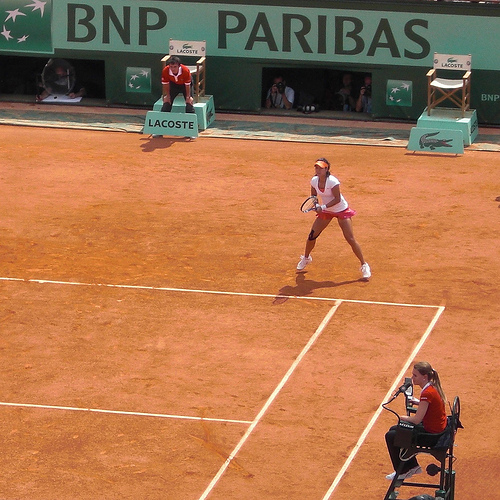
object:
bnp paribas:
[66, 3, 441, 60]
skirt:
[315, 208, 356, 216]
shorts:
[315, 206, 357, 219]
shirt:
[311, 175, 349, 214]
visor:
[314, 161, 328, 169]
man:
[35, 66, 86, 101]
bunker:
[1, 54, 107, 108]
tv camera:
[41, 55, 76, 95]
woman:
[384, 361, 447, 480]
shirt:
[418, 381, 447, 434]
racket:
[300, 196, 320, 213]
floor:
[3, 126, 294, 286]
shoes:
[360, 261, 371, 280]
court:
[0, 128, 500, 500]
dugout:
[262, 66, 373, 114]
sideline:
[200, 298, 342, 500]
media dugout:
[0, 55, 105, 101]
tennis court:
[1, 125, 498, 497]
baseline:
[1, 277, 446, 308]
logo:
[0, 1, 49, 45]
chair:
[426, 52, 472, 119]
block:
[416, 106, 479, 147]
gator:
[418, 131, 453, 151]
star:
[23, 0, 49, 18]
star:
[4, 8, 27, 22]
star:
[17, 35, 29, 44]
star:
[1, 24, 14, 42]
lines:
[0, 273, 445, 308]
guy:
[152, 56, 197, 140]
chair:
[160, 38, 206, 103]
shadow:
[272, 270, 369, 305]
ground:
[0, 122, 498, 498]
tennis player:
[295, 157, 371, 280]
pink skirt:
[315, 207, 356, 219]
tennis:
[0, 154, 374, 499]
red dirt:
[108, 150, 273, 240]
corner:
[0, 0, 64, 113]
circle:
[0, 0, 48, 44]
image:
[418, 131, 453, 150]